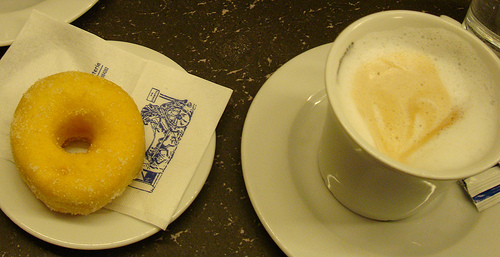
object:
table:
[0, 0, 499, 257]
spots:
[237, 225, 249, 237]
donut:
[8, 68, 154, 217]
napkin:
[1, 8, 239, 233]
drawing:
[126, 86, 202, 195]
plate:
[0, 38, 220, 253]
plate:
[239, 39, 500, 256]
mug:
[315, 9, 499, 223]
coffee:
[345, 46, 466, 169]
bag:
[456, 163, 500, 213]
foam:
[333, 24, 499, 173]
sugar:
[7, 67, 149, 219]